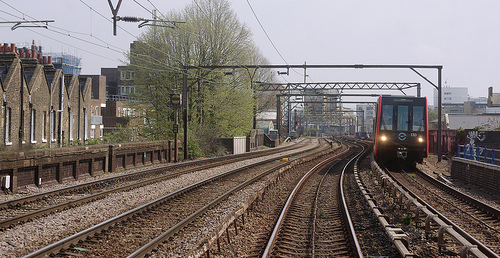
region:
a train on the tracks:
[371, 91, 428, 164]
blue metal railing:
[455, 145, 497, 160]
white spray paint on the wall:
[465, 132, 487, 157]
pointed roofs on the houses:
[0, 62, 104, 152]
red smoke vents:
[2, 43, 52, 63]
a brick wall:
[0, 140, 182, 191]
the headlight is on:
[378, 135, 388, 142]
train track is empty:
[262, 137, 366, 256]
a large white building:
[434, 83, 467, 105]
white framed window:
[30, 108, 37, 143]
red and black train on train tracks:
[356, 84, 441, 174]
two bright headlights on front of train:
[374, 128, 426, 148]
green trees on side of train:
[115, 5, 290, 166]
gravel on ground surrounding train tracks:
[0, 171, 187, 253]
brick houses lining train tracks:
[1, 42, 153, 147]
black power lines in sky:
[3, 1, 290, 89]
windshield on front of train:
[384, 100, 426, 133]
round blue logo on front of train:
[393, 129, 409, 144]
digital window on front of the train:
[385, 93, 422, 106]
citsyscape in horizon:
[289, 78, 371, 142]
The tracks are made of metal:
[217, 163, 277, 242]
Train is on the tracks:
[349, 52, 471, 217]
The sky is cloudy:
[300, 30, 408, 108]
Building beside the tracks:
[8, 46, 108, 137]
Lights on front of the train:
[379, 125, 454, 186]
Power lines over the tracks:
[100, 3, 255, 72]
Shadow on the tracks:
[310, 126, 445, 251]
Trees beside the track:
[140, 14, 262, 154]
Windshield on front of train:
[380, 90, 440, 147]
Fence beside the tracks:
[429, 113, 488, 178]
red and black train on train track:
[359, 86, 436, 172]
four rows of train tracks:
[0, 134, 498, 256]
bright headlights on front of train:
[367, 126, 434, 149]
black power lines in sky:
[2, 3, 137, 72]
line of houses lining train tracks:
[0, 42, 115, 162]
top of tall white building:
[430, 78, 470, 108]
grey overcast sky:
[299, 15, 465, 55]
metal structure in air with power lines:
[104, 2, 190, 42]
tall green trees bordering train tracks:
[121, 7, 290, 155]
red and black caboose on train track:
[372, 92, 432, 169]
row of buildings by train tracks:
[0, 55, 109, 158]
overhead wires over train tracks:
[0, 29, 313, 79]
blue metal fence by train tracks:
[455, 140, 499, 162]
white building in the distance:
[435, 83, 471, 105]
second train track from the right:
[261, 140, 366, 256]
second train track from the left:
[21, 133, 333, 256]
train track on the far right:
[386, 163, 498, 256]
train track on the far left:
[0, 133, 310, 233]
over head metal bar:
[181, 62, 445, 164]